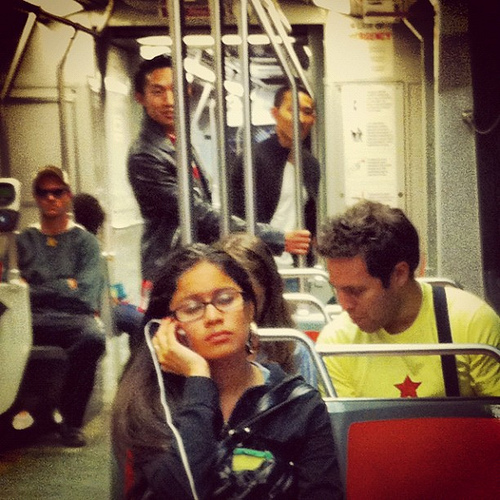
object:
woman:
[111, 241, 343, 499]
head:
[141, 242, 259, 364]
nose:
[203, 302, 225, 329]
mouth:
[205, 329, 235, 344]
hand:
[148, 315, 211, 381]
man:
[308, 200, 499, 397]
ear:
[392, 261, 410, 285]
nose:
[336, 289, 353, 315]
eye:
[347, 287, 364, 298]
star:
[395, 376, 422, 399]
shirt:
[309, 279, 499, 400]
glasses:
[168, 291, 255, 326]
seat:
[313, 345, 499, 497]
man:
[127, 54, 312, 316]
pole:
[287, 86, 307, 319]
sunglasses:
[37, 184, 64, 202]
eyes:
[217, 291, 236, 303]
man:
[14, 164, 103, 447]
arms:
[15, 226, 101, 311]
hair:
[315, 201, 421, 285]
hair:
[108, 245, 254, 464]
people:
[0, 55, 498, 500]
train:
[0, 0, 499, 497]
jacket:
[123, 116, 284, 281]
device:
[149, 318, 193, 348]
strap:
[430, 284, 460, 397]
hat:
[31, 163, 72, 193]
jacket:
[106, 364, 336, 499]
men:
[127, 54, 320, 284]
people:
[106, 201, 499, 500]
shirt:
[256, 159, 311, 267]